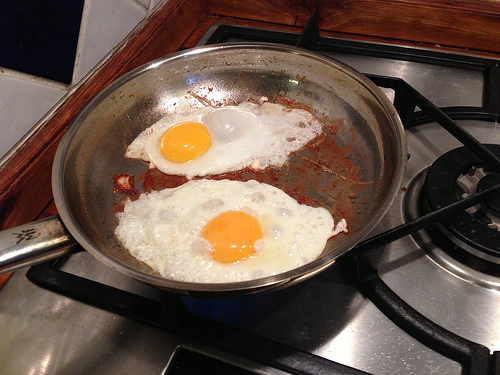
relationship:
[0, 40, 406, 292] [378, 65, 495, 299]
pan on stove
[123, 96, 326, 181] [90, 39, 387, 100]
egg in frying pan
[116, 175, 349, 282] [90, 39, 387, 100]
egg in frying pan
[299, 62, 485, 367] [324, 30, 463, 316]
grate on stove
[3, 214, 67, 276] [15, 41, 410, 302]
handle of frying pan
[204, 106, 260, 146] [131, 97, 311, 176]
bubble on egg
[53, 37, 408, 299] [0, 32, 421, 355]
eggs cooking pan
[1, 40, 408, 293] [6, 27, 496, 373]
pan on stove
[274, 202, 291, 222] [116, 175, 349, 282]
bubbles in egg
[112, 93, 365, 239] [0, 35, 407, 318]
marks in pan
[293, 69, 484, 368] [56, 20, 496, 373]
surface of stovetop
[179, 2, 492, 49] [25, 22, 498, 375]
border of gas stove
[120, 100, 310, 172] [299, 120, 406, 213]
egg frying pan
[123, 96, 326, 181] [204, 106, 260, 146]
egg with bubble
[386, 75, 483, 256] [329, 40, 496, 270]
unit on stove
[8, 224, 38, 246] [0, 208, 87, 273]
markings on handle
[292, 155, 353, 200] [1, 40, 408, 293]
grease in pan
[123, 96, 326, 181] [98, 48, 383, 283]
egg in a pan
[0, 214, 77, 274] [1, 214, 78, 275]
handle on a handle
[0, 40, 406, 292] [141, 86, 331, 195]
pan containing eggs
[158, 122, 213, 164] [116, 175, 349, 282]
egg yolks of an egg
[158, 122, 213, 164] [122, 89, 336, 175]
egg yolks of an egg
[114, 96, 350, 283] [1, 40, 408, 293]
eggs on pan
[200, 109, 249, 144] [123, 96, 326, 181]
bubble in egg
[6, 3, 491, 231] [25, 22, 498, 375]
border on side gas stove